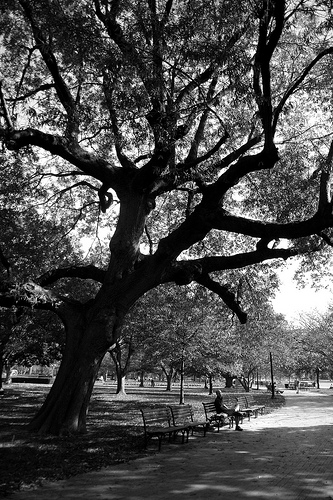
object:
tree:
[2, 85, 333, 437]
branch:
[254, 89, 279, 152]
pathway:
[250, 412, 318, 425]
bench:
[140, 402, 180, 454]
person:
[295, 377, 300, 394]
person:
[214, 389, 243, 431]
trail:
[244, 367, 303, 463]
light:
[267, 320, 285, 399]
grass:
[107, 405, 132, 448]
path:
[110, 464, 160, 500]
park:
[100, 330, 287, 469]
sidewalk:
[301, 388, 330, 500]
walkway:
[220, 446, 256, 497]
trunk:
[37, 323, 115, 422]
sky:
[301, 290, 318, 309]